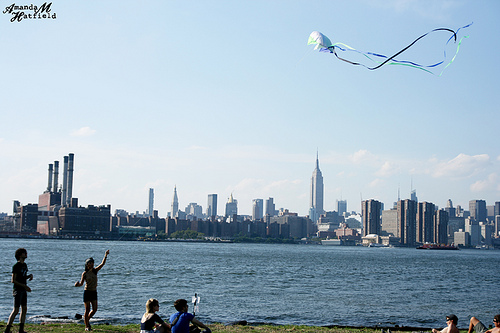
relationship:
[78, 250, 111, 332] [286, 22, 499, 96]
woman points at kite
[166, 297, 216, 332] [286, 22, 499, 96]
man watch kite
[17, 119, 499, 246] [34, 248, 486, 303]
buildings across water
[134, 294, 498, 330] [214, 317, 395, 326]
people lying on grass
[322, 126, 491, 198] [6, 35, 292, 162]
clouds in sky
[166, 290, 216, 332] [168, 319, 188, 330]
man has back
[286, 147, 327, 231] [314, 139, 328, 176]
building has tip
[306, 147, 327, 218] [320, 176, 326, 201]
building have edge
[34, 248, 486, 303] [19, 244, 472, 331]
water near park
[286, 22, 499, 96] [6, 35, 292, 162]
kite in sky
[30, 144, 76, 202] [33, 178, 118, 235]
smokestacks on building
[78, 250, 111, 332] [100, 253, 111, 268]
woman extends hand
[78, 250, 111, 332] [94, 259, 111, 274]
woman has arm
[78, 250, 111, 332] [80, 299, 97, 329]
woman has legs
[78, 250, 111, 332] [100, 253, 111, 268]
woman has hand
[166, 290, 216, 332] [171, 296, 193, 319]
man has head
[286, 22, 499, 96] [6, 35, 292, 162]
kite flying in sky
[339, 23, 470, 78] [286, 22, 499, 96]
streamers behind kite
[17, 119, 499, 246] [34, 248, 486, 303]
buildings near water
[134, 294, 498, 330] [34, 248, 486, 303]
people sitting near water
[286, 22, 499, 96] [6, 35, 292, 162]
kite flies in sky